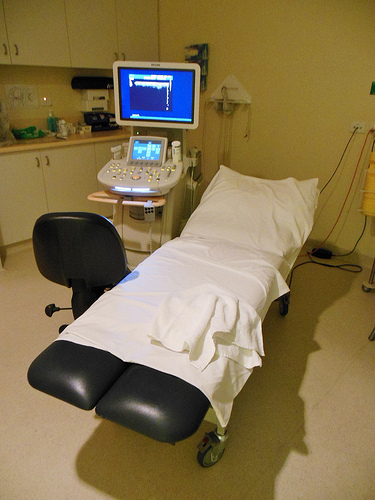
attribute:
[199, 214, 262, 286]
sheet — white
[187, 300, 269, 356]
towel — white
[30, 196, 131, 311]
chair — black, rollable, cushioned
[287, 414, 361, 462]
floor — tiled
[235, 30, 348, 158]
wall — yellow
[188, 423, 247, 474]
wheels — black, locable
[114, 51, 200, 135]
monitor — large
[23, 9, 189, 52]
cabinets — white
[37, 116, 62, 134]
sanitizer — green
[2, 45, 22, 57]
handles — silver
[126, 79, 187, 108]
screen — blue